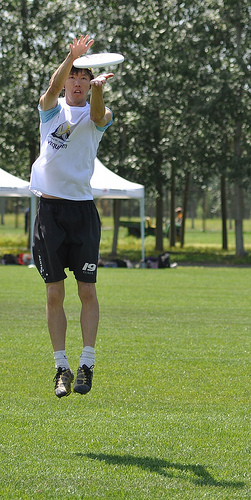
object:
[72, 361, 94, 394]
feet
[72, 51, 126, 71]
frisbee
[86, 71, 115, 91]
hand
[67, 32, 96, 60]
hands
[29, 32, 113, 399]
man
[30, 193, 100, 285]
shorts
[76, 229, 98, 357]
legs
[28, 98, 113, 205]
shirt